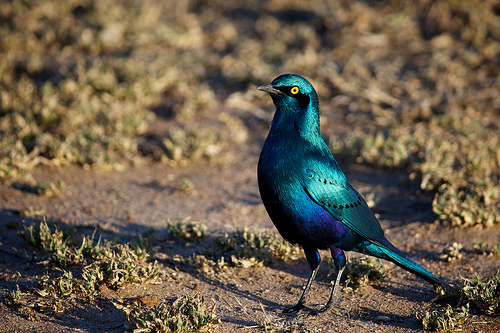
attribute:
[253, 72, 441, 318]
bird — small, beautiful, shiny, purple, blue green, blue, standing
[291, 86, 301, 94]
eye — small, yellow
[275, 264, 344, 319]
feet — grey, black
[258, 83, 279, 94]
beak — small, sharp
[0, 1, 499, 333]
ground — dry, sandy, brown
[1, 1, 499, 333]
grass — scattered, green, short, patchy, brown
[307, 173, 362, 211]
dots — black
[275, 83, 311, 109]
markings — black